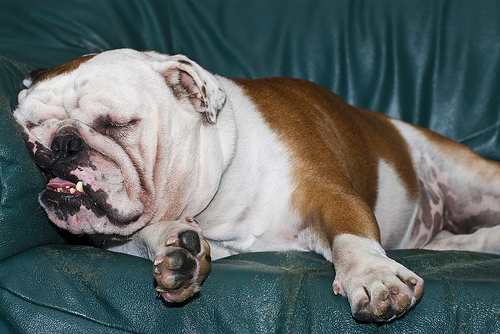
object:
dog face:
[13, 80, 150, 234]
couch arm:
[0, 2, 118, 259]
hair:
[97, 57, 161, 99]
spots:
[177, 60, 196, 68]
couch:
[2, 2, 497, 332]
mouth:
[36, 171, 97, 206]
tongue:
[46, 174, 78, 192]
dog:
[10, 46, 498, 323]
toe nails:
[155, 267, 160, 273]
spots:
[200, 85, 214, 100]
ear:
[159, 54, 227, 126]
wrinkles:
[113, 138, 185, 219]